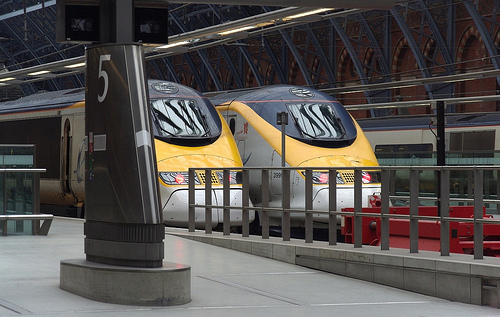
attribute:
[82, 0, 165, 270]
post — metal 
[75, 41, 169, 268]
sign — informative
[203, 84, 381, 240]
train — yellow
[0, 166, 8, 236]
pole — metal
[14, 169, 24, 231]
pole — metal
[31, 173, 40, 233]
pole — metal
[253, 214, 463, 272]
track — train track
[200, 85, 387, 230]
rail — light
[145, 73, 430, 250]
light rails — identical, side by side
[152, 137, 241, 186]
paint — yellow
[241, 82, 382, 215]
front — sloped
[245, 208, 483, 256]
tracks — train